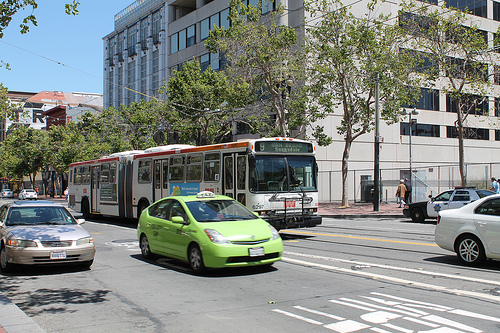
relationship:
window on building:
[446, 22, 486, 47] [99, 0, 499, 201]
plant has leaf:
[0, 122, 50, 173] [12, 138, 29, 150]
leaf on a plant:
[87, 127, 102, 141] [86, 57, 258, 152]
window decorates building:
[492, 0, 500, 21] [99, 0, 499, 201]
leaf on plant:
[82, 147, 93, 156] [72, 107, 127, 214]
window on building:
[492, 0, 500, 21] [99, 0, 499, 201]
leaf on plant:
[176, 75, 257, 110] [212, 31, 310, 131]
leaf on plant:
[314, 124, 325, 129] [370, 0, 491, 190]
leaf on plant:
[17, 132, 26, 141] [0, 119, 57, 188]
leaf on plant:
[53, 114, 89, 136] [304, 0, 429, 217]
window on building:
[492, 0, 500, 21] [167, 2, 498, 200]